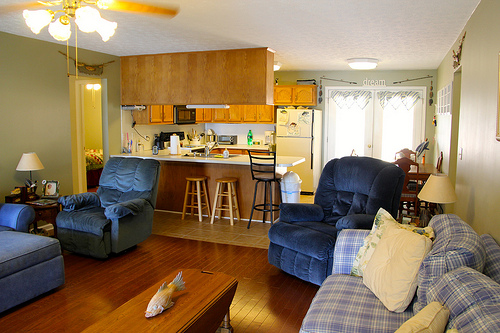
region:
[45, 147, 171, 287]
a blue reclining chair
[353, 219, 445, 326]
a white pillow on a couch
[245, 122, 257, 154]
a green plastic bottle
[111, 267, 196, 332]
a statue of a fish on a table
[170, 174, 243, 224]
two wooden bar stools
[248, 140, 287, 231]
a black metal bar stool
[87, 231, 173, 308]
hard wood floors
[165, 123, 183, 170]
a roll of paper towels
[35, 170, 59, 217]
a picture frame on a table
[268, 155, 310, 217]
a white garbage can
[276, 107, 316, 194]
A white refrigerator.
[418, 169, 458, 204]
A white lamp shade.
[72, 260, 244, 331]
A wooden coffee table.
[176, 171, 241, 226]
Wooden bar stools.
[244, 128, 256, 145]
A green bottle of Sprite on the counter.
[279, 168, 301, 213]
A white trash can.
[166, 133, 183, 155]
A roll of paper towels.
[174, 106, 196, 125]
A black microwave.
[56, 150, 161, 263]
A blue reclining arm chair.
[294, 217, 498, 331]
A blue and white plaid sofa.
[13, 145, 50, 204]
lamp on end table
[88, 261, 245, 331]
wooden coffee table with folding sides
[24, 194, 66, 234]
small brown end table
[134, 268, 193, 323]
decorative fish on coffee table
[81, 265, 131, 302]
dark brown hard wood floor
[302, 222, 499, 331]
blue and white plaid couch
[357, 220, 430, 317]
white throw pillow on couch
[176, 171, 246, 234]
two bar stools under bar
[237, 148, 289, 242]
tall black bar stool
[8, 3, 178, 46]
ceiling fan and light fixture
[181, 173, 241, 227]
wooden bar stools under the counter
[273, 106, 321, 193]
a white refrigerator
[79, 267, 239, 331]
a wooden coffee table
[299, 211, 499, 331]
a light blue couch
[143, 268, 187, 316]
a fish decoration on the coffee table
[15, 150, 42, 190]
a lamp in the corner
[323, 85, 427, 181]
doors with large windows next to the kitchen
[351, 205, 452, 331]
pillows on the couch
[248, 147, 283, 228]
a tall chair next to the bar stools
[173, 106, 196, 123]
a black microwave in the kitchen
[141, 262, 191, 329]
fish table decoration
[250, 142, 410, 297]
blue cushioned cordoroy recliner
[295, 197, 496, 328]
light blue checkered sofa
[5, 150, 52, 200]
table lamp with white shade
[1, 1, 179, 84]
ceiling fan with four lights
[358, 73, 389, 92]
word home decor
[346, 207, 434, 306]
two white pillows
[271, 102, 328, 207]
white refigerator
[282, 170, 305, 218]
small white trashcan under kitchen counter